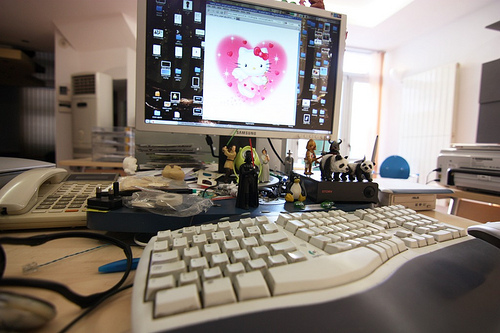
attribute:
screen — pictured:
[124, 0, 353, 142]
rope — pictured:
[57, 273, 138, 330]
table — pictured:
[0, 208, 485, 328]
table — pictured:
[316, 282, 490, 329]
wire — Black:
[11, 266, 129, 305]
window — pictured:
[294, 47, 378, 169]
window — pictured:
[203, 0, 302, 125]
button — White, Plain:
[267, 236, 382, 291]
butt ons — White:
[101, 184, 490, 321]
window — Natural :
[326, 33, 421, 161]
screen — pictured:
[139, 0, 336, 136]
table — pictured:
[368, 172, 456, 203]